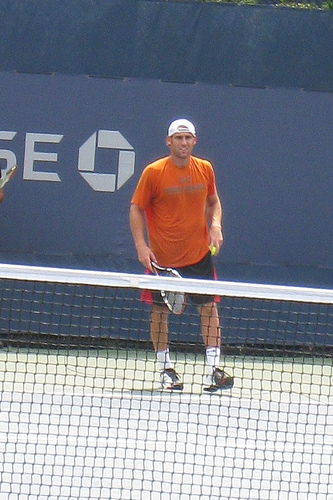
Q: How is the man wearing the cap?
A: Backwards.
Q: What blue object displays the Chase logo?
A: Tarp.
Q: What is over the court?
A: The net.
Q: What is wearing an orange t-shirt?
A: The boy.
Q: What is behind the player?
A: The blue wall.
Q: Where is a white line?
A: Above the tennis net.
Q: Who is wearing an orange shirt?
A: Tennis player.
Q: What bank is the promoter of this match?
A: Chase bank.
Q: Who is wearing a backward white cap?
A: Tennis player.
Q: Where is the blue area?
A: Background of the scene.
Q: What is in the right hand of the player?
A: Tennis racquet.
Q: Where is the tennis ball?
A: Left hand of the player.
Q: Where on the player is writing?
A: On his shirt.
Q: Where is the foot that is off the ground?
A: Left foot.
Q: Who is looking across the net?
A: Tennis player.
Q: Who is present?
A: Player.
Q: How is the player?
A: In motion.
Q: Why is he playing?
A: Fun.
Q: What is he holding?
A: Ball.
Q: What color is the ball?
A: Green.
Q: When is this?
A: Daytime.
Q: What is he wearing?
A: Shorts.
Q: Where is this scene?
A: Male tennis match.